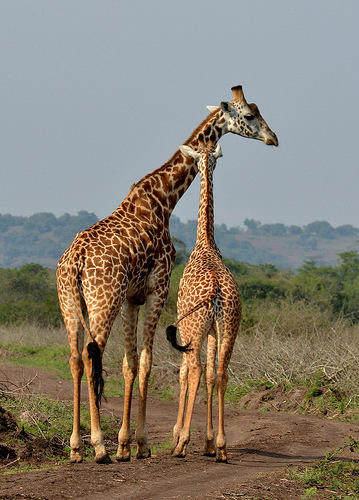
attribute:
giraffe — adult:
[61, 102, 258, 355]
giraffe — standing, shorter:
[153, 144, 244, 479]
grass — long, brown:
[1, 310, 351, 407]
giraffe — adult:
[37, 74, 313, 395]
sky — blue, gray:
[1, 2, 357, 233]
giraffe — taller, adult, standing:
[47, 81, 283, 468]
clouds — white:
[21, 45, 155, 152]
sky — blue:
[284, 20, 341, 66]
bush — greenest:
[0, 249, 357, 330]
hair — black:
[165, 325, 194, 351]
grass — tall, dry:
[252, 307, 357, 396]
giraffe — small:
[167, 137, 245, 472]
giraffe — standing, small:
[170, 145, 236, 461]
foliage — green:
[245, 228, 350, 312]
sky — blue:
[2, 1, 167, 150]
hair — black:
[87, 340, 109, 410]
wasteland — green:
[4, 259, 355, 498]